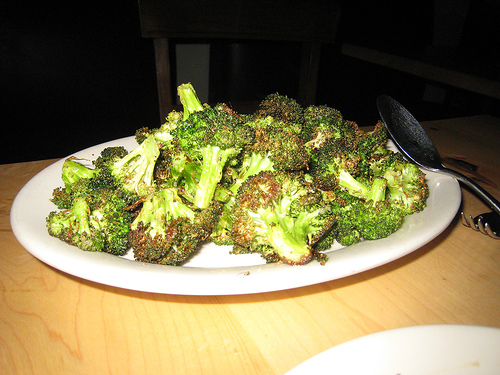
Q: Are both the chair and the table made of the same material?
A: Yes, both the chair and the table are made of wood.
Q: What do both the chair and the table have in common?
A: The material, both the chair and the table are wooden.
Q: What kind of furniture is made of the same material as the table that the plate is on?
A: The chair is made of the same material as the table.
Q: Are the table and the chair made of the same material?
A: Yes, both the table and the chair are made of wood.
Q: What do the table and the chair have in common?
A: The material, both the table and the chair are wooden.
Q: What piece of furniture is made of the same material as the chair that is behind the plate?
A: The table is made of the same material as the chair.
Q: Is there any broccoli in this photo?
A: Yes, there is broccoli.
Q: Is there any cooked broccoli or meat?
A: Yes, there is cooked broccoli.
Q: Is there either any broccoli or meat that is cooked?
A: Yes, the broccoli is cooked.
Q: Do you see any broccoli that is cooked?
A: Yes, there is cooked broccoli.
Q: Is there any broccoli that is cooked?
A: Yes, there is broccoli that is cooked.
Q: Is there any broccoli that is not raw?
A: Yes, there is cooked broccoli.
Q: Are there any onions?
A: No, there are no onions.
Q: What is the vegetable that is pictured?
A: The vegetable is broccoli.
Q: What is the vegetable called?
A: The vegetable is broccoli.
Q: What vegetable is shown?
A: The vegetable is broccoli.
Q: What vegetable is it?
A: The vegetable is broccoli.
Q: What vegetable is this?
A: This is broccoli.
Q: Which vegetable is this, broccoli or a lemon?
A: This is broccoli.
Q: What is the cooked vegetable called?
A: The vegetable is broccoli.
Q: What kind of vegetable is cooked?
A: The vegetable is broccoli.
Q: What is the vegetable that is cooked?
A: The vegetable is broccoli.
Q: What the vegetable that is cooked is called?
A: The vegetable is broccoli.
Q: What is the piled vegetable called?
A: The vegetable is broccoli.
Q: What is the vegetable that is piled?
A: The vegetable is broccoli.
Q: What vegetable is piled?
A: The vegetable is broccoli.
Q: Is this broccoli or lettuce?
A: This is broccoli.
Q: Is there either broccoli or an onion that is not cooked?
A: No, there is broccoli but it is cooked.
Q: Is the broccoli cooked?
A: Yes, the broccoli is cooked.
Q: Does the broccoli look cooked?
A: Yes, the broccoli is cooked.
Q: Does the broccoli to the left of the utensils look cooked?
A: Yes, the broccoli is cooked.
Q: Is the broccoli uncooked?
A: No, the broccoli is cooked.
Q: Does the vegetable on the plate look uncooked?
A: No, the broccoli is cooked.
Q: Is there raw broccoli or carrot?
A: No, there is broccoli but it is cooked.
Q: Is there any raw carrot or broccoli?
A: No, there is broccoli but it is cooked.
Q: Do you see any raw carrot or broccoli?
A: No, there is broccoli but it is cooked.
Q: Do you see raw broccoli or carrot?
A: No, there is broccoli but it is cooked.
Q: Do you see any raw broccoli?
A: No, there is broccoli but it is cooked.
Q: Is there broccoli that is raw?
A: No, there is broccoli but it is cooked.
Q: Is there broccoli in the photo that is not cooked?
A: No, there is broccoli but it is cooked.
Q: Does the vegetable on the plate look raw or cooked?
A: The broccoli is cooked.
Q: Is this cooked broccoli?
A: Yes, this is cooked broccoli.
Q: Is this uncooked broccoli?
A: No, this is cooked broccoli.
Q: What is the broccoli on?
A: The broccoli is on the plate.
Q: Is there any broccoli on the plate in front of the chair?
A: Yes, there is broccoli on the plate.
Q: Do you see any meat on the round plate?
A: No, there is broccoli on the plate.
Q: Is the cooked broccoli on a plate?
A: Yes, the broccoli is on a plate.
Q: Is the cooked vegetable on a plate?
A: Yes, the broccoli is on a plate.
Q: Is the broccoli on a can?
A: No, the broccoli is on a plate.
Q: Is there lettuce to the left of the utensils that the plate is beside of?
A: No, there is broccoli to the left of the utensils.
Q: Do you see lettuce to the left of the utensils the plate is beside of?
A: No, there is broccoli to the left of the utensils.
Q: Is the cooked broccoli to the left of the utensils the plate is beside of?
A: Yes, the broccoli is to the left of the utensils.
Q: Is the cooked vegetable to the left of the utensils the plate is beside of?
A: Yes, the broccoli is to the left of the utensils.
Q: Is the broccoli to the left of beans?
A: No, the broccoli is to the left of the utensils.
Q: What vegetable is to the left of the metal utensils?
A: The vegetable is broccoli.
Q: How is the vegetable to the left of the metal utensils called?
A: The vegetable is broccoli.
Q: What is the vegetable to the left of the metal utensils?
A: The vegetable is broccoli.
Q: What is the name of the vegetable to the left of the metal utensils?
A: The vegetable is broccoli.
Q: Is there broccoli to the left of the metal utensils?
A: Yes, there is broccoli to the left of the utensils.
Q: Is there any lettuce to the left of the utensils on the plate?
A: No, there is broccoli to the left of the utensils.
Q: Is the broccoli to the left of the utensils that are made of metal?
A: Yes, the broccoli is to the left of the utensils.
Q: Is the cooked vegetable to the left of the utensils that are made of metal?
A: Yes, the broccoli is to the left of the utensils.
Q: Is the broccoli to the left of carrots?
A: No, the broccoli is to the left of the utensils.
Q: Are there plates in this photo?
A: Yes, there is a plate.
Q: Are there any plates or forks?
A: Yes, there is a plate.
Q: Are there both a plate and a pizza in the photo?
A: No, there is a plate but no pizzas.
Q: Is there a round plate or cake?
A: Yes, there is a round plate.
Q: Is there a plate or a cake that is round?
A: Yes, the plate is round.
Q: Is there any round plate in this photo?
A: Yes, there is a round plate.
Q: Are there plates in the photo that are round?
A: Yes, there is a plate that is round.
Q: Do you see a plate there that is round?
A: Yes, there is a plate that is round.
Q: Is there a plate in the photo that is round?
A: Yes, there is a plate that is round.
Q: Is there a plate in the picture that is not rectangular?
A: Yes, there is a round plate.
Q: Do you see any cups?
A: No, there are no cups.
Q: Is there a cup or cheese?
A: No, there are no cups or cheese.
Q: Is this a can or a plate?
A: This is a plate.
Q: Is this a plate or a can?
A: This is a plate.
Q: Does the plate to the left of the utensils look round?
A: Yes, the plate is round.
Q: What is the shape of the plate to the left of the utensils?
A: The plate is round.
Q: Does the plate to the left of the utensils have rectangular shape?
A: No, the plate is round.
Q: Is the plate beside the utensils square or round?
A: The plate is round.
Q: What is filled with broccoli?
A: The plate is filled with broccoli.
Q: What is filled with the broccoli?
A: The plate is filled with broccoli.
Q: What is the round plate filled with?
A: The plate is filled with broccoli.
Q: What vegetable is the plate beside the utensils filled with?
A: The plate is filled with broccoli.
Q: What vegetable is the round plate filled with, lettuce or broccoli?
A: The plate is filled with broccoli.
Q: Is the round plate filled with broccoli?
A: Yes, the plate is filled with broccoli.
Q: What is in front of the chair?
A: The plate is in front of the chair.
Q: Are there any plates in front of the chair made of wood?
A: Yes, there is a plate in front of the chair.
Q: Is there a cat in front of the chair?
A: No, there is a plate in front of the chair.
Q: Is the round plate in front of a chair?
A: Yes, the plate is in front of a chair.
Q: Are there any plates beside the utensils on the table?
A: Yes, there is a plate beside the utensils.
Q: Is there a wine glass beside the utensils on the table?
A: No, there is a plate beside the utensils.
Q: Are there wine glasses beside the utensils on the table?
A: No, there is a plate beside the utensils.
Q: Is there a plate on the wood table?
A: Yes, there is a plate on the table.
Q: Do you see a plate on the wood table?
A: Yes, there is a plate on the table.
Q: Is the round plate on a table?
A: Yes, the plate is on a table.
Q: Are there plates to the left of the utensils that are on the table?
A: Yes, there is a plate to the left of the utensils.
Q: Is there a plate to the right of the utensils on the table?
A: No, the plate is to the left of the utensils.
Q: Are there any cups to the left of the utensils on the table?
A: No, there is a plate to the left of the utensils.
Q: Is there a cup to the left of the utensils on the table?
A: No, there is a plate to the left of the utensils.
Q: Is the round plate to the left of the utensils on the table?
A: Yes, the plate is to the left of the utensils.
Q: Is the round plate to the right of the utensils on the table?
A: No, the plate is to the left of the utensils.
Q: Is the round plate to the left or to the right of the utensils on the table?
A: The plate is to the left of the utensils.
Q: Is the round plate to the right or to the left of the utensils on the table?
A: The plate is to the left of the utensils.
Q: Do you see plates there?
A: Yes, there is a plate.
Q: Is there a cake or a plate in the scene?
A: Yes, there is a plate.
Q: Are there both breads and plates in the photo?
A: No, there is a plate but no breads.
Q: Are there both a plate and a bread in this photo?
A: No, there is a plate but no breads.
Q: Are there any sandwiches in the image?
A: No, there are no sandwiches.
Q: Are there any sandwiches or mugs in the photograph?
A: No, there are no sandwiches or mugs.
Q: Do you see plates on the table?
A: Yes, there is a plate on the table.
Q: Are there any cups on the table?
A: No, there is a plate on the table.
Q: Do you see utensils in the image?
A: Yes, there are utensils.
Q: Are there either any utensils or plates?
A: Yes, there are utensils.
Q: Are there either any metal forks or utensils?
A: Yes, there are metal utensils.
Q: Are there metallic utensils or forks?
A: Yes, there are metal utensils.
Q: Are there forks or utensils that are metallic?
A: Yes, the utensils are metallic.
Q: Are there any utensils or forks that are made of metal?
A: Yes, the utensils are made of metal.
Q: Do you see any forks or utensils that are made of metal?
A: Yes, the utensils are made of metal.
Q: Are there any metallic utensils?
A: Yes, there are metal utensils.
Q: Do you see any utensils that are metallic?
A: Yes, there are metal utensils.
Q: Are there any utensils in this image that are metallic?
A: Yes, there are utensils that are metallic.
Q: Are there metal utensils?
A: Yes, there are utensils that are made of metal.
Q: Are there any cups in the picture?
A: No, there are no cups.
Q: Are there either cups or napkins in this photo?
A: No, there are no cups or napkins.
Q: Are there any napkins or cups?
A: No, there are no cups or napkins.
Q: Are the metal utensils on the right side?
A: Yes, the utensils are on the right of the image.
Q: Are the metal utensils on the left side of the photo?
A: No, the utensils are on the right of the image.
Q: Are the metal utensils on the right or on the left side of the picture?
A: The utensils are on the right of the image.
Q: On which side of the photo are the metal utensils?
A: The utensils are on the right of the image.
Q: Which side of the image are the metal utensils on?
A: The utensils are on the right of the image.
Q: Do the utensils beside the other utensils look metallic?
A: Yes, the utensils are metallic.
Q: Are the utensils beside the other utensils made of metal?
A: Yes, the utensils are made of metal.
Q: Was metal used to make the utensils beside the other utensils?
A: Yes, the utensils are made of metal.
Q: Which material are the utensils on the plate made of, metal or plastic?
A: The utensils are made of metal.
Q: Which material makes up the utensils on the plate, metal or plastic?
A: The utensils are made of metal.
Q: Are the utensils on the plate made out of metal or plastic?
A: The utensils are made of metal.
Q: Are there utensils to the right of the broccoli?
A: Yes, there are utensils to the right of the broccoli.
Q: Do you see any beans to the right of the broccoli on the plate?
A: No, there are utensils to the right of the broccoli.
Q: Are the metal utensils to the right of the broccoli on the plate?
A: Yes, the utensils are to the right of the broccoli.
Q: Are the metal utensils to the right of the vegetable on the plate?
A: Yes, the utensils are to the right of the broccoli.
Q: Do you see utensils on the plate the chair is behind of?
A: Yes, there are utensils on the plate.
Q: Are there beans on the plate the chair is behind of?
A: No, there are utensils on the plate.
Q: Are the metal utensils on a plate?
A: Yes, the utensils are on a plate.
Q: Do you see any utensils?
A: Yes, there are utensils.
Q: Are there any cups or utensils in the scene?
A: Yes, there are utensils.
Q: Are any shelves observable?
A: No, there are no shelves.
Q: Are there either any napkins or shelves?
A: No, there are no shelves or napkins.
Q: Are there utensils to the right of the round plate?
A: Yes, there are utensils to the right of the plate.